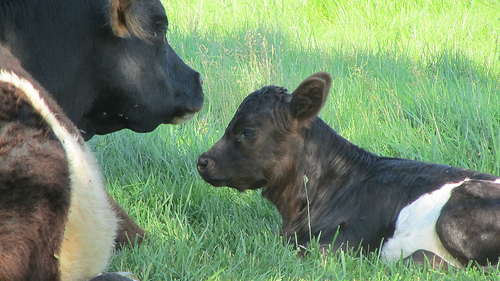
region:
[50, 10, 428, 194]
two cows sitting together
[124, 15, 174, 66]
eye of large adult cow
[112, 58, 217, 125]
snout of large black cow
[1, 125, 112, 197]
white and brown body of cow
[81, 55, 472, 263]
small cow laying on ground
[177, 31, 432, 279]
baby cow on ground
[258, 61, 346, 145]
small ears perked up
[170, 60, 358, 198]
small cow looking forward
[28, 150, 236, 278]
tall grass on terrain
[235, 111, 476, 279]
brown and white torso of cow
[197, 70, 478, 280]
Baby cow lying in the grass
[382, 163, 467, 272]
White spot on a black cow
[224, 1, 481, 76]
Grassy field in cow pasture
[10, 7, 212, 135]
Momma cow watching over her baby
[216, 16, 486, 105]
Shadow cast on the ground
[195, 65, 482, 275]
Young cow laying in a pasture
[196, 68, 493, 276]
Cow resting in a pasture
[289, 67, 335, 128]
Ears of a young cow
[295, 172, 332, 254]
Weed growing taller than the grass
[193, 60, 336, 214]
Cute face of a young cow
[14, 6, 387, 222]
cow and baby cow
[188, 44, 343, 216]
profile of infant cow's head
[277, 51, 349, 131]
ears on a brown cow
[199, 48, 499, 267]
brown and white calf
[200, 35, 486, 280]
calf lying in green grass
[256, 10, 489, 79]
sunlight on green grass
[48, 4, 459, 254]
two cows in a meadow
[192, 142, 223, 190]
nostrile of a baby cow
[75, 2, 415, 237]
big cow looking at calf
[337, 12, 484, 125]
sun and shadow on grass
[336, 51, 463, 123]
the grass is green and visible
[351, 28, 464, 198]
the grass is green and visible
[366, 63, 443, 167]
the grass is green and visible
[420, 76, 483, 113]
the grass is green and visible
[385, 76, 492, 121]
the grass is green and visible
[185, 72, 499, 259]
young calf laying down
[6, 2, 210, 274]
adult cow laying in field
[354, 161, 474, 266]
white spots on cow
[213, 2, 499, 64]
green grass in field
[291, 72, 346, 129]
ears of cow sticking up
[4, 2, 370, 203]
adult cow looking at baby cow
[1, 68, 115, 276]
white spots on brown cow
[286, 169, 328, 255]
weed touch side of cow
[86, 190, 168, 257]
cow's leg in green grass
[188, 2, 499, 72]
sun shining on green grass